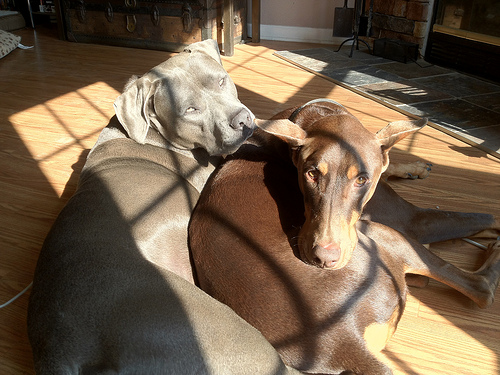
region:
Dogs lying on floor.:
[28, 37, 499, 374]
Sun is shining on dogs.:
[23, 42, 498, 372]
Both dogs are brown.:
[32, 35, 499, 373]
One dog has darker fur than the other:
[31, 37, 493, 373]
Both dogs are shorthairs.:
[23, 34, 487, 374]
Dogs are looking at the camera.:
[18, 36, 498, 372]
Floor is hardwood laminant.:
[2, 1, 499, 372]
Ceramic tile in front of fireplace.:
[271, 0, 498, 165]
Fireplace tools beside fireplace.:
[323, 0, 430, 69]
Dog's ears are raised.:
[246, 88, 414, 280]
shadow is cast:
[2, 67, 237, 323]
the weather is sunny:
[11, 50, 486, 359]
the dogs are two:
[58, 46, 458, 373]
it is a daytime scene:
[9, 34, 497, 373]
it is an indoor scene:
[11, 36, 499, 370]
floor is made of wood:
[30, 103, 90, 141]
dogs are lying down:
[60, 40, 480, 372]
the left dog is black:
[12, 38, 217, 371]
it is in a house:
[38, 36, 496, 331]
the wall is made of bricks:
[383, 14, 430, 40]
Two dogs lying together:
[38, 45, 498, 373]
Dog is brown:
[195, 74, 497, 372]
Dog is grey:
[20, 27, 284, 374]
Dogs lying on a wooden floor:
[15, 32, 495, 373]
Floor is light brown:
[0, 24, 498, 374]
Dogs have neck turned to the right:
[190, 90, 493, 373]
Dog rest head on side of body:
[270, 105, 415, 285]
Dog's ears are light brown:
[257, 101, 431, 155]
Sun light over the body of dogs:
[8, 18, 498, 373]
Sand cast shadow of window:
[17, 35, 402, 150]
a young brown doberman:
[205, 78, 499, 365]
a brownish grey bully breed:
[54, 55, 306, 369]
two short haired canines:
[33, 25, 498, 354]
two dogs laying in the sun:
[56, 42, 480, 374]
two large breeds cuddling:
[44, 33, 458, 370]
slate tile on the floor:
[268, 30, 498, 153]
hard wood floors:
[1, 110, 76, 203]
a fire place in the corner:
[408, 1, 498, 100]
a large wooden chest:
[28, 0, 277, 61]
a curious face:
[250, 92, 437, 273]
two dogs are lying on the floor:
[41, 39, 497, 374]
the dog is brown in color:
[258, 107, 423, 331]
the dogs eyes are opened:
[305, 165, 377, 182]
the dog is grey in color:
[36, 54, 206, 373]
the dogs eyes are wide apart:
[256, 116, 439, 147]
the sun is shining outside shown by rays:
[434, 333, 477, 372]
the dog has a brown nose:
[310, 241, 347, 264]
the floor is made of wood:
[0, 63, 88, 128]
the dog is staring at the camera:
[298, 170, 389, 189]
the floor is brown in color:
[17, 54, 84, 160]